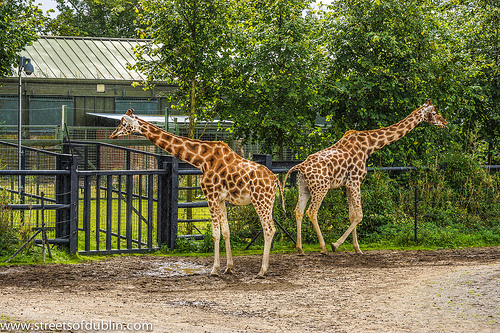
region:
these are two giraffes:
[104, 98, 456, 275]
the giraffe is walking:
[293, 100, 440, 252]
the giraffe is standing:
[113, 102, 279, 280]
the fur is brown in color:
[211, 151, 233, 197]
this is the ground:
[208, 289, 435, 329]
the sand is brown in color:
[62, 279, 177, 315]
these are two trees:
[231, 6, 486, 94]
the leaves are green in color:
[232, 21, 383, 91]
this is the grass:
[382, 221, 460, 237]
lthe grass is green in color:
[387, 227, 454, 250]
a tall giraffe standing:
[278, 100, 446, 257]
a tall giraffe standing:
[108, 102, 286, 279]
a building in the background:
[0, 35, 362, 181]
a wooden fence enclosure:
[0, 135, 495, 250]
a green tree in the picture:
[131, 0, 258, 159]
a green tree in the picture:
[221, 0, 326, 160]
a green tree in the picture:
[323, 5, 458, 165]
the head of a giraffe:
[104, 104, 139, 140]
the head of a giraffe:
[413, 99, 451, 134]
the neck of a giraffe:
[378, 113, 422, 142]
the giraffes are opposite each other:
[97, 90, 444, 250]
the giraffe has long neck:
[157, 138, 194, 152]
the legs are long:
[211, 210, 278, 255]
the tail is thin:
[283, 165, 297, 182]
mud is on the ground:
[138, 261, 203, 283]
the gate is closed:
[70, 170, 171, 232]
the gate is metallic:
[73, 174, 168, 242]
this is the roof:
[67, 45, 124, 71]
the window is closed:
[128, 100, 162, 110]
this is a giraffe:
[296, 127, 371, 246]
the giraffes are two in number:
[131, 112, 406, 251]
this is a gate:
[78, 145, 171, 245]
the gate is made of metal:
[94, 167, 149, 245]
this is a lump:
[26, 60, 32, 76]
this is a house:
[47, 39, 107, 124]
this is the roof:
[60, 36, 114, 66]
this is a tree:
[256, 14, 303, 141]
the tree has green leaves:
[266, 72, 278, 97]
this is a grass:
[58, 253, 77, 260]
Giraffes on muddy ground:
[83, 110, 417, 275]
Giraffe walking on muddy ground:
[295, 80, 455, 256]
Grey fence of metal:
[0, 170, 230, 249]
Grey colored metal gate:
[77, 172, 164, 257]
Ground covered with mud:
[7, 246, 434, 321]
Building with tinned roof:
[18, 37, 169, 79]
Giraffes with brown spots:
[113, 96, 453, 278]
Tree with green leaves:
[133, 0, 249, 137]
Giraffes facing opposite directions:
[108, 99, 448, 276]